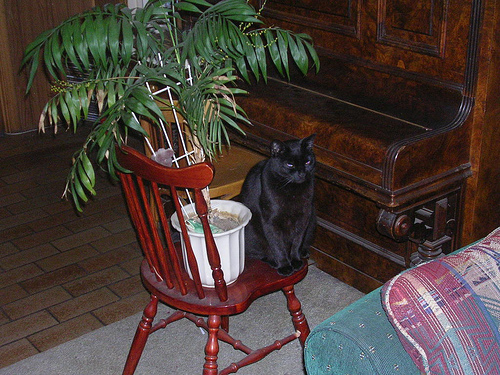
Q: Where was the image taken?
A: It was taken at the living room.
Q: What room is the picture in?
A: It is at the living room.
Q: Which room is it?
A: It is a living room.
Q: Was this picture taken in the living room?
A: Yes, it was taken in the living room.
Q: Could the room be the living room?
A: Yes, it is the living room.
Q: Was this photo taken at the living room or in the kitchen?
A: It was taken at the living room.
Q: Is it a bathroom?
A: No, it is a living room.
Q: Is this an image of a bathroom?
A: No, the picture is showing a living room.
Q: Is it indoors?
A: Yes, it is indoors.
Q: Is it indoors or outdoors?
A: It is indoors.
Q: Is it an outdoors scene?
A: No, it is indoors.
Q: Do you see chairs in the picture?
A: Yes, there is a chair.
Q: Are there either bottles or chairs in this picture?
A: Yes, there is a chair.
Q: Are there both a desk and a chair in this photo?
A: No, there is a chair but no desks.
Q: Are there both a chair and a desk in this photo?
A: No, there is a chair but no desks.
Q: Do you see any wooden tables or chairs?
A: Yes, there is a wood chair.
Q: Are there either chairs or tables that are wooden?
A: Yes, the chair is wooden.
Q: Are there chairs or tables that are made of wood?
A: Yes, the chair is made of wood.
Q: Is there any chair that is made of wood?
A: Yes, there is a chair that is made of wood.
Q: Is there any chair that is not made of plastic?
A: Yes, there is a chair that is made of wood.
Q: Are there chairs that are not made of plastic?
A: Yes, there is a chair that is made of wood.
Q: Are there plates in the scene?
A: No, there are no plates.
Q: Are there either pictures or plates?
A: No, there are no plates or pictures.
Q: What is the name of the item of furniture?
A: The piece of furniture is a chair.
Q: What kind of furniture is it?
A: The piece of furniture is a chair.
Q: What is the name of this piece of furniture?
A: This is a chair.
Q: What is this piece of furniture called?
A: This is a chair.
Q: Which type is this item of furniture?
A: This is a chair.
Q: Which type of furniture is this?
A: This is a chair.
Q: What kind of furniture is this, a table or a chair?
A: This is a chair.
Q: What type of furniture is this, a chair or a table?
A: This is a chair.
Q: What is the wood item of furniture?
A: The piece of furniture is a chair.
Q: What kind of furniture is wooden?
A: The furniture is a chair.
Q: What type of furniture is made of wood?
A: The furniture is a chair.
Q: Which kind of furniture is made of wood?
A: The furniture is a chair.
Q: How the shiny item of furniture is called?
A: The piece of furniture is a chair.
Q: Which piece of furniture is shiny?
A: The piece of furniture is a chair.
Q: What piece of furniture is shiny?
A: The piece of furniture is a chair.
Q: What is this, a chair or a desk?
A: This is a chair.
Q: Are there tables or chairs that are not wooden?
A: No, there is a chair but it is wooden.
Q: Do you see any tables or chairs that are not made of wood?
A: No, there is a chair but it is made of wood.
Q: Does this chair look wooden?
A: Yes, the chair is wooden.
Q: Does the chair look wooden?
A: Yes, the chair is wooden.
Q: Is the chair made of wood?
A: Yes, the chair is made of wood.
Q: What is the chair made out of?
A: The chair is made of wood.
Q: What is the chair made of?
A: The chair is made of wood.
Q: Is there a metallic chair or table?
A: No, there is a chair but it is wooden.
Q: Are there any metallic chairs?
A: No, there is a chair but it is wooden.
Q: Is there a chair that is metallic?
A: No, there is a chair but it is wooden.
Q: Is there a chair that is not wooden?
A: No, there is a chair but it is wooden.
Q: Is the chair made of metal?
A: No, the chair is made of wood.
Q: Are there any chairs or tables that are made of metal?
A: No, there is a chair but it is made of wood.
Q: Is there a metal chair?
A: No, there is a chair but it is made of wood.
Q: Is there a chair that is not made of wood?
A: No, there is a chair but it is made of wood.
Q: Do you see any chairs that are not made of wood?
A: No, there is a chair but it is made of wood.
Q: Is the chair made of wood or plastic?
A: The chair is made of wood.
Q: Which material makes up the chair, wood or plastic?
A: The chair is made of wood.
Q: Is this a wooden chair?
A: Yes, this is a wooden chair.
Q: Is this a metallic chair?
A: No, this is a wooden chair.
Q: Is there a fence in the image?
A: No, there are no fences.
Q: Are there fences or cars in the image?
A: No, there are no fences or cars.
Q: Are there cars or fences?
A: No, there are no fences or cars.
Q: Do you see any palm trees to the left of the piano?
A: Yes, there is a palm tree to the left of the piano.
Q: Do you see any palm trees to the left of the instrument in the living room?
A: Yes, there is a palm tree to the left of the piano.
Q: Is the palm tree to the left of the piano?
A: Yes, the palm tree is to the left of the piano.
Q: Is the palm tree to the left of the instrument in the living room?
A: Yes, the palm tree is to the left of the piano.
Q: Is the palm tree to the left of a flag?
A: No, the palm tree is to the left of the piano.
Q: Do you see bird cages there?
A: No, there are no bird cages.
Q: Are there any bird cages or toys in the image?
A: No, there are no bird cages or toys.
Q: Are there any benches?
A: Yes, there is a bench.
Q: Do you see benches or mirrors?
A: Yes, there is a bench.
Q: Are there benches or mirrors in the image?
A: Yes, there is a bench.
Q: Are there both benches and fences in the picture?
A: No, there is a bench but no fences.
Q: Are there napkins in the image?
A: No, there are no napkins.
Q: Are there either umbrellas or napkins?
A: No, there are no napkins or umbrellas.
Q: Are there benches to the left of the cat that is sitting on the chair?
A: Yes, there is a bench to the left of the cat.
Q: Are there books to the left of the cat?
A: No, there is a bench to the left of the cat.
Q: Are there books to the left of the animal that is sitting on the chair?
A: No, there is a bench to the left of the cat.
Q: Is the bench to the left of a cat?
A: Yes, the bench is to the left of a cat.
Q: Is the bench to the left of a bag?
A: No, the bench is to the left of a cat.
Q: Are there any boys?
A: No, there are no boys.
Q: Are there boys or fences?
A: No, there are no boys or fences.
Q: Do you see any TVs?
A: No, there are no tvs.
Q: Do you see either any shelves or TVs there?
A: No, there are no TVs or shelves.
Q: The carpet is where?
A: The carpet is on the ground.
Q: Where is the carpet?
A: The carpet is on the ground.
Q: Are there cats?
A: Yes, there is a cat.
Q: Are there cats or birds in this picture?
A: Yes, there is a cat.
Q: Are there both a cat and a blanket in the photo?
A: No, there is a cat but no blankets.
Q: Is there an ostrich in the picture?
A: No, there are no ostriches.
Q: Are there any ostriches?
A: No, there are no ostriches.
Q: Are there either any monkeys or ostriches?
A: No, there are no ostriches or monkeys.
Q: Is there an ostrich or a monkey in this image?
A: No, there are no ostriches or monkeys.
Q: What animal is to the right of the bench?
A: The animal is a cat.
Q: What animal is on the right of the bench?
A: The animal is a cat.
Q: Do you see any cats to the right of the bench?
A: Yes, there is a cat to the right of the bench.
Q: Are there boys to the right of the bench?
A: No, there is a cat to the right of the bench.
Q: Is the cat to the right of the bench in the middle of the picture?
A: Yes, the cat is to the right of the bench.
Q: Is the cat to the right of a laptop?
A: No, the cat is to the right of the bench.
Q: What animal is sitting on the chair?
A: The cat is sitting on the chair.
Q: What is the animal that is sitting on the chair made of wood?
A: The animal is a cat.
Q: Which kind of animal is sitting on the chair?
A: The animal is a cat.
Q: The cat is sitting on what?
A: The cat is sitting on the chair.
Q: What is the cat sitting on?
A: The cat is sitting on the chair.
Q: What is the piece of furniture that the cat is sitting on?
A: The piece of furniture is a chair.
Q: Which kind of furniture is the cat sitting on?
A: The cat is sitting on the chair.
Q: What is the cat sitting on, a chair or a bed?
A: The cat is sitting on a chair.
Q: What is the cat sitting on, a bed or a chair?
A: The cat is sitting on a chair.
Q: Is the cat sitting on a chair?
A: Yes, the cat is sitting on a chair.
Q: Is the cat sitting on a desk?
A: No, the cat is sitting on a chair.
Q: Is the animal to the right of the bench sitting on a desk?
A: No, the cat is sitting on a chair.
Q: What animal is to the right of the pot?
A: The animal is a cat.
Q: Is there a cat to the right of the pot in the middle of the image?
A: Yes, there is a cat to the right of the pot.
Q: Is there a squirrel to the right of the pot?
A: No, there is a cat to the right of the pot.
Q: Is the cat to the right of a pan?
A: No, the cat is to the right of a pot.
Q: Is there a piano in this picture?
A: Yes, there is a piano.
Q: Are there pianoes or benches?
A: Yes, there is a piano.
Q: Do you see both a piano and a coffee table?
A: No, there is a piano but no coffee tables.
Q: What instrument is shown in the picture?
A: The instrument is a piano.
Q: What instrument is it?
A: The instrument is a piano.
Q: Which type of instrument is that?
A: That is a piano.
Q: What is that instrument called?
A: That is a piano.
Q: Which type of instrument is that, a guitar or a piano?
A: That is a piano.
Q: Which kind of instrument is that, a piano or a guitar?
A: That is a piano.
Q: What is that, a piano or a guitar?
A: That is a piano.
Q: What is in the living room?
A: The piano is in the living room.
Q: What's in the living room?
A: The piano is in the living room.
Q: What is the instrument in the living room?
A: The instrument is a piano.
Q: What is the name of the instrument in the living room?
A: The instrument is a piano.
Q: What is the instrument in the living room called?
A: The instrument is a piano.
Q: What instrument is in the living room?
A: The instrument is a piano.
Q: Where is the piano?
A: The piano is in the living room.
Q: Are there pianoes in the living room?
A: Yes, there is a piano in the living room.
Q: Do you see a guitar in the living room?
A: No, there is a piano in the living room.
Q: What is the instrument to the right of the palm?
A: The instrument is a piano.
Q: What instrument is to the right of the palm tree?
A: The instrument is a piano.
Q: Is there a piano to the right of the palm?
A: Yes, there is a piano to the right of the palm.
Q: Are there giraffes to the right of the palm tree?
A: No, there is a piano to the right of the palm tree.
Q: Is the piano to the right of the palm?
A: Yes, the piano is to the right of the palm.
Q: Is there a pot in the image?
A: Yes, there is a pot.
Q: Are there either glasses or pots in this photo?
A: Yes, there is a pot.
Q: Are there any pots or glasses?
A: Yes, there is a pot.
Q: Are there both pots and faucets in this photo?
A: No, there is a pot but no faucets.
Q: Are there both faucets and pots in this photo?
A: No, there is a pot but no faucets.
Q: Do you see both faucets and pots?
A: No, there is a pot but no faucets.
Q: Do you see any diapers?
A: No, there are no diapers.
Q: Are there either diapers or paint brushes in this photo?
A: No, there are no diapers or paint brushes.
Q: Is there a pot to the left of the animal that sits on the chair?
A: Yes, there is a pot to the left of the cat.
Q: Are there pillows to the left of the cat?
A: No, there is a pot to the left of the cat.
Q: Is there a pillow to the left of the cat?
A: No, there is a pot to the left of the cat.